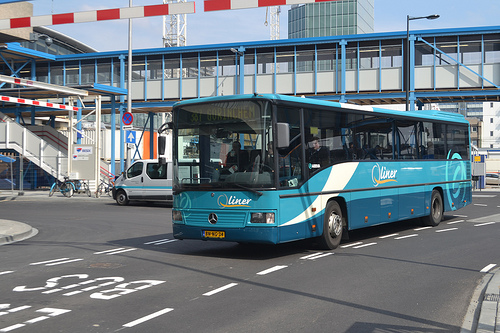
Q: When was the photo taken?
A: Afternoon.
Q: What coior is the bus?
A: Blue and black.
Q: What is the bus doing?
A: Moving.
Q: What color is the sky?
A: Blue.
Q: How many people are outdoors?
A: None.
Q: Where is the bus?
A: On the street.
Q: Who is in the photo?
A: People on a bus.